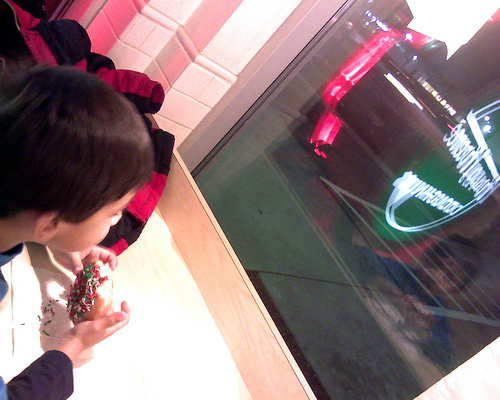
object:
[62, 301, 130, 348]
hand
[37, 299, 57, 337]
sprinkles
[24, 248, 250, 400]
table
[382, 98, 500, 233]
logo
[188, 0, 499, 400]
window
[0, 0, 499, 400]
doughnut shop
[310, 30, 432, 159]
red light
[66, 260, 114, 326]
donut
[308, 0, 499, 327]
reflection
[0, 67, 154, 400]
boy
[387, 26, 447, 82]
store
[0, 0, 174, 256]
coat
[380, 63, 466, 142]
restaurant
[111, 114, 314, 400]
counter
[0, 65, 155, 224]
black hair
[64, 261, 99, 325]
sprinkle